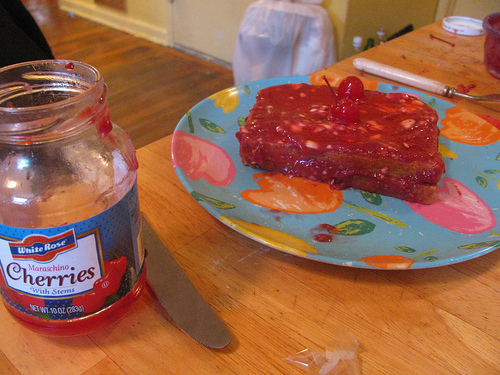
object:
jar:
[0, 58, 148, 339]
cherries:
[330, 76, 367, 121]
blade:
[140, 215, 231, 348]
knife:
[59, 146, 235, 349]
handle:
[351, 55, 456, 98]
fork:
[350, 51, 500, 102]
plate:
[170, 74, 500, 273]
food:
[235, 70, 447, 206]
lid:
[440, 14, 489, 36]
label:
[0, 174, 151, 321]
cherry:
[336, 75, 366, 97]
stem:
[320, 75, 337, 99]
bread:
[235, 83, 446, 206]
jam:
[273, 144, 387, 195]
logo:
[8, 226, 79, 262]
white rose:
[14, 237, 69, 255]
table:
[0, 17, 500, 374]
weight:
[24, 304, 85, 316]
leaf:
[331, 218, 376, 236]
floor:
[34, 5, 235, 152]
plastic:
[232, 0, 336, 84]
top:
[169, 281, 241, 353]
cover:
[443, 14, 488, 36]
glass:
[0, 58, 147, 337]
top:
[183, 239, 457, 330]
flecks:
[299, 134, 327, 158]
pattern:
[241, 171, 421, 239]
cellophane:
[277, 330, 366, 373]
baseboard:
[57, 0, 174, 48]